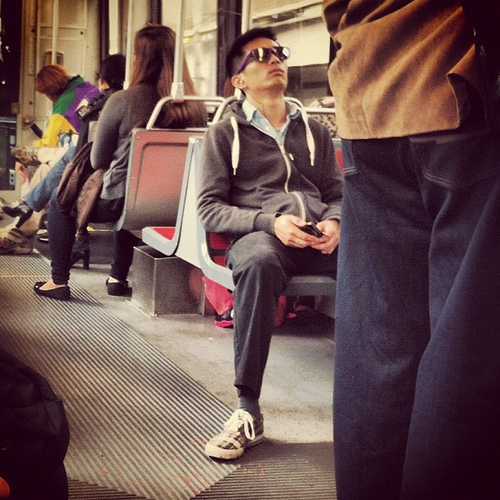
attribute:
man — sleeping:
[235, 38, 347, 341]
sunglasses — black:
[231, 38, 302, 70]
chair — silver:
[189, 135, 342, 302]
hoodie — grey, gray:
[204, 107, 359, 271]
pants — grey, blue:
[229, 217, 340, 373]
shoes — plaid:
[196, 400, 266, 469]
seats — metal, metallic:
[101, 83, 330, 328]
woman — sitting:
[77, 26, 207, 263]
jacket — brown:
[322, 11, 499, 168]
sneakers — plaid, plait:
[198, 409, 289, 481]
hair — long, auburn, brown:
[120, 34, 211, 123]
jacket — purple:
[33, 92, 111, 172]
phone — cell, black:
[290, 215, 330, 255]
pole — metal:
[149, 10, 210, 90]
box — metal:
[122, 244, 225, 333]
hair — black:
[217, 21, 308, 71]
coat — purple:
[51, 69, 109, 134]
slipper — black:
[33, 280, 84, 304]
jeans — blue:
[14, 148, 101, 288]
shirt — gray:
[85, 92, 201, 215]